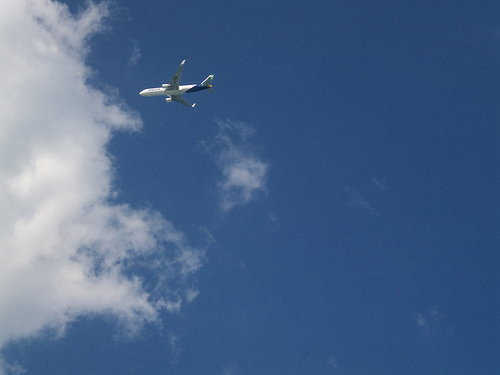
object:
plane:
[139, 60, 214, 108]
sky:
[219, 0, 500, 375]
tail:
[201, 75, 214, 92]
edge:
[86, 3, 145, 360]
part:
[86, 3, 374, 57]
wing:
[168, 95, 191, 108]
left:
[178, 60, 185, 69]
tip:
[139, 89, 146, 97]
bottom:
[139, 86, 211, 97]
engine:
[162, 84, 170, 88]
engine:
[166, 98, 172, 102]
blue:
[185, 84, 209, 93]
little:
[217, 121, 264, 202]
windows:
[148, 88, 153, 91]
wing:
[170, 60, 186, 84]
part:
[201, 75, 214, 85]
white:
[139, 87, 164, 96]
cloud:
[0, 0, 201, 344]